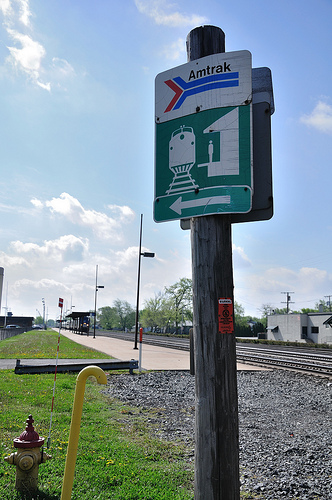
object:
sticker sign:
[214, 297, 235, 337]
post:
[186, 22, 245, 499]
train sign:
[150, 49, 277, 229]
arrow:
[164, 192, 232, 216]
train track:
[72, 323, 332, 381]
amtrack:
[186, 58, 235, 84]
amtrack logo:
[161, 67, 240, 115]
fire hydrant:
[7, 413, 51, 495]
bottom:
[4, 449, 57, 496]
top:
[13, 410, 45, 449]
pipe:
[59, 362, 107, 500]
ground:
[0, 369, 330, 499]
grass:
[0, 325, 124, 366]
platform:
[49, 320, 274, 373]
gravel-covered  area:
[107, 361, 332, 500]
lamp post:
[130, 207, 155, 351]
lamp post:
[91, 264, 107, 341]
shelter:
[54, 309, 94, 338]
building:
[268, 313, 331, 343]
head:
[137, 248, 155, 261]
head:
[97, 283, 105, 290]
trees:
[107, 285, 258, 336]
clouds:
[22, 203, 129, 294]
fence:
[0, 326, 38, 342]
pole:
[46, 293, 67, 455]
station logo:
[161, 105, 240, 199]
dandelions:
[95, 455, 105, 463]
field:
[0, 376, 154, 496]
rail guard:
[13, 357, 140, 378]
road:
[0, 359, 120, 367]